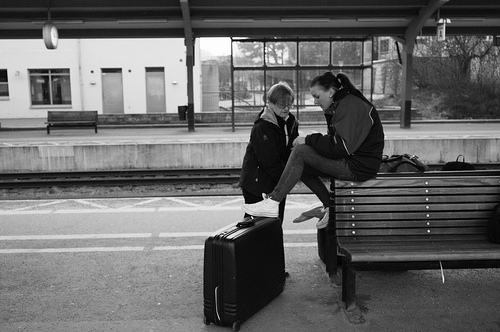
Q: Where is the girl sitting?
A: On a bench.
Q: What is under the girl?
A: Slatted bench.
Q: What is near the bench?
A: Suitcase.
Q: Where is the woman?
A: On the bench.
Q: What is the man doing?
A: Looking at the woman.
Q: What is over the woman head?
A: Roof.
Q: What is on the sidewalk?
A: White markings.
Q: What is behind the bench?
A: A tree.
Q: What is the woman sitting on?
A: Bench.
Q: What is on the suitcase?
A: Wheels.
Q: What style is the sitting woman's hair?
A: A ponytail.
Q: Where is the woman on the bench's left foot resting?
A: A suitcase.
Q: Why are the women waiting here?
A: For a train.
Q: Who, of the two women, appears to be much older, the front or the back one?
A: The back one.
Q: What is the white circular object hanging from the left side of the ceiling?
A: A clock.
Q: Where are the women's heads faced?
A: Downwards.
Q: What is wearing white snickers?
A: The woman.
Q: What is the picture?
A: Black and white.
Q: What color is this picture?
A: Black and white.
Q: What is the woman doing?
A: Waiting.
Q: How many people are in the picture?
A: Two.